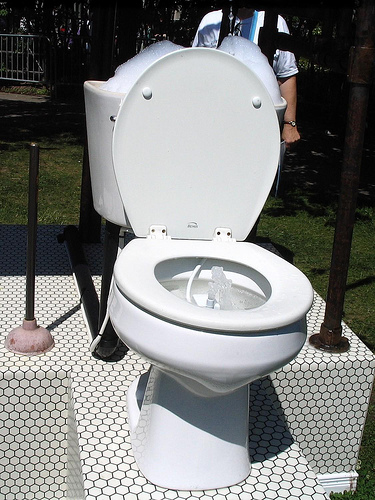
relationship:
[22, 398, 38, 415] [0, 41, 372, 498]
tile in restroom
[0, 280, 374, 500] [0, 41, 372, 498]
tile in restroom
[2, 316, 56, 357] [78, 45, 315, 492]
sponger for toilet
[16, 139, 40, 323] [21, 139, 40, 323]
handle has handle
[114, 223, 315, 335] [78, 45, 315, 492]
seat on toilet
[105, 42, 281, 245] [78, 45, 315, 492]
lid on toilet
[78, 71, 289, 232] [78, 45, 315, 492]
tank on toilet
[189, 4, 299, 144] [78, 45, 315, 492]
person walking behind toilet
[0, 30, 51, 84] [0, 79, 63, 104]
railing beside sidewalk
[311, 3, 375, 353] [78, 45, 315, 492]
pipe next to toilet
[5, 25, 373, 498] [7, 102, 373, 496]
display on grass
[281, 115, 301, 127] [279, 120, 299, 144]
watch on hand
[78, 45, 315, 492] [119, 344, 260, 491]
toilet on base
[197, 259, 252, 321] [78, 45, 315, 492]
water in toilet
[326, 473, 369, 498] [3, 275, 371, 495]
weeds near floor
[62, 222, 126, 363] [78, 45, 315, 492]
pipe behind toilet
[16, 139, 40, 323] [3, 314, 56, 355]
handle on plunger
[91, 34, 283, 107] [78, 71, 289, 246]
soap bubbling up tank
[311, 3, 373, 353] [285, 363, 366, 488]
pipe in floor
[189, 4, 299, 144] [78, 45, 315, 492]
person behind toilet